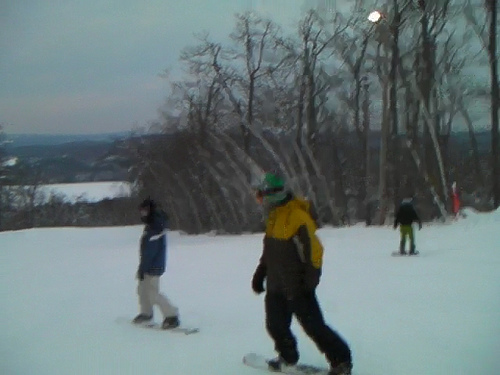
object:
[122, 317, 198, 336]
skis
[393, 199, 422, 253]
person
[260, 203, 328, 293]
jacket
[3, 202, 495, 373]
snow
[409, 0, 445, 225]
trees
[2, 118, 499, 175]
mountains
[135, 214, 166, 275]
jacket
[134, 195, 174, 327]
man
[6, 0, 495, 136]
sky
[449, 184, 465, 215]
sign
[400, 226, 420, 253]
pants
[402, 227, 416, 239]
green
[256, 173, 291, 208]
helmet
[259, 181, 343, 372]
man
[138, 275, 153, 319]
leg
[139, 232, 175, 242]
stripe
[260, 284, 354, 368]
pants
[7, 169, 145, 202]
snow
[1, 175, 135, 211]
area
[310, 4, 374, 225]
trees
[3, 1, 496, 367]
place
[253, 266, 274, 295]
glove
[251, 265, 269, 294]
hand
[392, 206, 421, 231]
jacket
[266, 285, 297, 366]
legs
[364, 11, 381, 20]
light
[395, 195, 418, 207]
hat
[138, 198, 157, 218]
hat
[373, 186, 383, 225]
people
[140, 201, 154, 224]
mask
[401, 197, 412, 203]
mask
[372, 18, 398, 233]
pole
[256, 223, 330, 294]
bottom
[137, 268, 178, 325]
pants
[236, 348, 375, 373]
snowboard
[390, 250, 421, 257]
snowboard